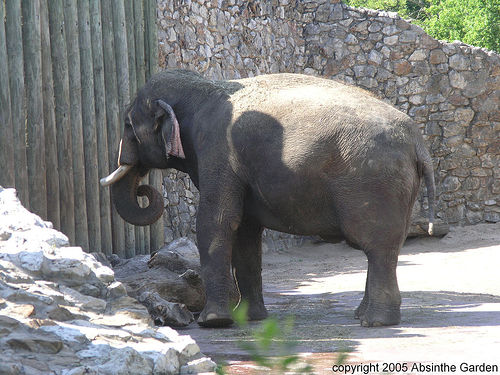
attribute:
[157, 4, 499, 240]
wall — white, grey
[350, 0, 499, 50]
trees — green, far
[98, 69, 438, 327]
elephant — on, close, massive, looking, big, large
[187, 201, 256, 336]
leg — on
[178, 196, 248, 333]
leg — on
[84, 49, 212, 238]
head — on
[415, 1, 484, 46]
trees — behind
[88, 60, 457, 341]
elephant — in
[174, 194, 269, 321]
leg — on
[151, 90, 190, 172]
ear — on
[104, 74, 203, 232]
head — on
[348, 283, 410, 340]
foot — on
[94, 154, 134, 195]
tusk — on